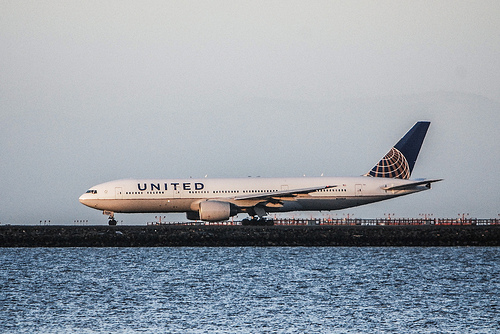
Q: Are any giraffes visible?
A: No, there are no giraffes.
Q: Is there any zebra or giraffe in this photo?
A: No, there are no giraffes or zebras.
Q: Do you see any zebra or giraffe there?
A: No, there are no giraffes or zebras.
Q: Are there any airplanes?
A: Yes, there is an airplane.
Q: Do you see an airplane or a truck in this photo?
A: Yes, there is an airplane.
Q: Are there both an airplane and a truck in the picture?
A: No, there is an airplane but no trucks.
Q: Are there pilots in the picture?
A: No, there are no pilots.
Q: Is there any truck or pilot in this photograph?
A: No, there are no pilots or trucks.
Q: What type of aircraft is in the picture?
A: The aircraft is an airplane.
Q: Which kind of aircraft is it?
A: The aircraft is an airplane.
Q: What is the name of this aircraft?
A: This is an airplane.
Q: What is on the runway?
A: The airplane is on the runway.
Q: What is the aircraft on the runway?
A: The aircraft is an airplane.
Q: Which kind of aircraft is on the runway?
A: The aircraft is an airplane.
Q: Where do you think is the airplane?
A: The airplane is on the runway.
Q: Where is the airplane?
A: The airplane is on the runway.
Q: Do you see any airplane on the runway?
A: Yes, there is an airplane on the runway.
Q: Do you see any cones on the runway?
A: No, there is an airplane on the runway.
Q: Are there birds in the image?
A: No, there are no birds.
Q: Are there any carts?
A: No, there are no carts.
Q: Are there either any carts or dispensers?
A: No, there are no carts or dispensers.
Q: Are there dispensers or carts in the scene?
A: No, there are no carts or dispensers.